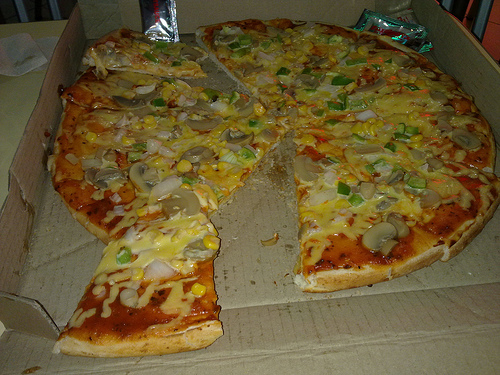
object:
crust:
[52, 320, 228, 359]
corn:
[191, 282, 206, 296]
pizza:
[47, 17, 498, 354]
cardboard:
[223, 192, 298, 300]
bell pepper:
[116, 245, 132, 265]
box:
[0, 0, 499, 375]